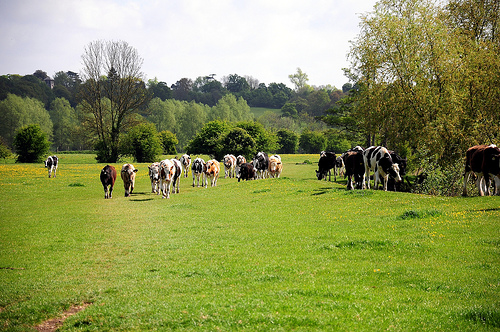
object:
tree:
[342, 0, 497, 198]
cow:
[147, 162, 161, 194]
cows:
[192, 157, 205, 188]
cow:
[203, 159, 220, 189]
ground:
[411, 145, 455, 187]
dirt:
[23, 293, 125, 330]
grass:
[0, 152, 499, 329]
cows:
[180, 153, 192, 178]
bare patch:
[28, 302, 95, 331]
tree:
[75, 38, 159, 163]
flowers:
[3, 166, 32, 173]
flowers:
[425, 205, 483, 225]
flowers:
[372, 266, 379, 274]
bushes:
[1, 92, 347, 154]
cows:
[237, 163, 255, 182]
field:
[8, 156, 498, 327]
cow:
[223, 154, 237, 179]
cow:
[343, 148, 364, 190]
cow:
[43, 155, 59, 178]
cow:
[121, 163, 138, 197]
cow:
[159, 160, 177, 200]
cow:
[315, 151, 337, 182]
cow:
[361, 145, 403, 191]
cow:
[462, 144, 500, 197]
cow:
[100, 164, 118, 199]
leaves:
[431, 133, 443, 139]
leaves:
[37, 143, 44, 149]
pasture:
[0, 153, 483, 330]